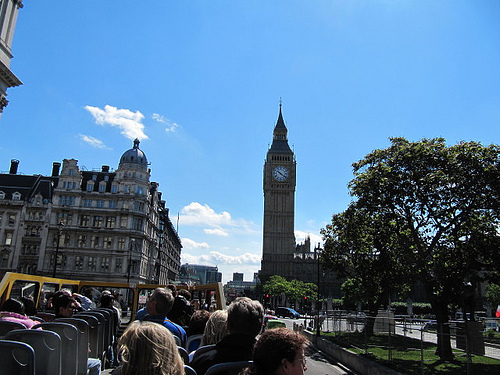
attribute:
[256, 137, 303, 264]
pillar — long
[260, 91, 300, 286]
clock — white 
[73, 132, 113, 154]
cloud — white 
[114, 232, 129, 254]
window — small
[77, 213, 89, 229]
window — small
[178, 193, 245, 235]
white cloud — Small 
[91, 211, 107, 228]
window — small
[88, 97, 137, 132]
clouds — very few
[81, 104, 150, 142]
cloud — white 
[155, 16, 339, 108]
cloud — white 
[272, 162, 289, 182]
clock — big 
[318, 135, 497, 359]
tree — large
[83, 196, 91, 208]
window — small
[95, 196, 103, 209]
window — small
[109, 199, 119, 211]
window — small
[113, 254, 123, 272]
window — small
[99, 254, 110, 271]
window — small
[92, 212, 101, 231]
window — small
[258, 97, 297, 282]
building — tall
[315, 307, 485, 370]
fence — enclosed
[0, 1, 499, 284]
view — clear